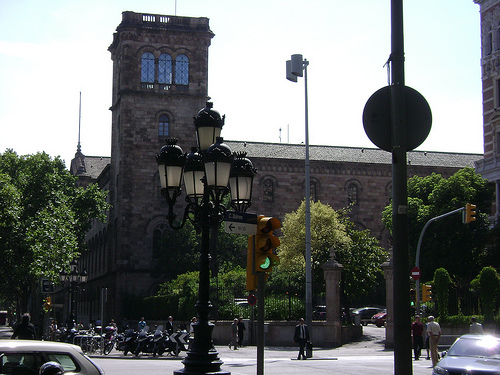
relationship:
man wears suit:
[290, 316, 312, 361] [291, 324, 311, 358]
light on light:
[257, 254, 273, 273] [252, 254, 275, 271]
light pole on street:
[285, 52, 315, 359] [41, 339, 473, 374]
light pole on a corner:
[285, 52, 315, 359] [273, 271, 391, 366]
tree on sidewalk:
[1, 148, 110, 344] [0, 321, 345, 361]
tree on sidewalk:
[0, 171, 17, 332] [0, 321, 345, 361]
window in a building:
[140, 47, 158, 87] [104, 7, 217, 340]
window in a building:
[156, 49, 173, 87] [104, 7, 217, 340]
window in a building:
[174, 51, 193, 90] [104, 7, 217, 340]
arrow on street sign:
[227, 219, 239, 232] [223, 208, 258, 239]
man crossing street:
[290, 316, 312, 361] [41, 339, 473, 374]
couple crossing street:
[227, 313, 247, 349] [41, 339, 473, 374]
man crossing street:
[425, 315, 442, 371] [41, 339, 473, 374]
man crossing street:
[410, 312, 426, 363] [41, 339, 473, 374]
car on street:
[1, 338, 104, 374] [41, 339, 473, 374]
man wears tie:
[290, 316, 312, 361] [300, 324, 306, 343]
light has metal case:
[201, 135, 233, 209] [196, 134, 236, 223]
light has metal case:
[227, 172, 253, 204] [224, 150, 255, 213]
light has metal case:
[180, 166, 206, 201] [181, 145, 205, 199]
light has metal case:
[156, 165, 185, 190] [156, 136, 187, 207]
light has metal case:
[194, 125, 223, 154] [192, 100, 227, 151]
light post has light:
[182, 213, 221, 369] [227, 172, 253, 204]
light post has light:
[182, 213, 221, 369] [180, 166, 206, 201]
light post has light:
[182, 213, 221, 369] [201, 135, 233, 209]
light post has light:
[182, 213, 221, 369] [156, 165, 185, 190]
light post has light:
[182, 213, 221, 369] [194, 125, 223, 154]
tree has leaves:
[281, 192, 352, 325] [278, 199, 352, 270]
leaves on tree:
[380, 168, 494, 271] [379, 164, 495, 315]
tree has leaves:
[1, 148, 110, 344] [18, 151, 116, 284]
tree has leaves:
[0, 171, 17, 332] [1, 170, 24, 258]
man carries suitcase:
[290, 316, 312, 361] [304, 340, 314, 362]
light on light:
[256, 234, 276, 253] [252, 254, 275, 271]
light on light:
[260, 219, 274, 236] [252, 254, 275, 271]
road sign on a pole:
[410, 266, 421, 283] [410, 202, 463, 327]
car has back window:
[1, 338, 104, 374] [47, 351, 80, 374]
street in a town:
[41, 339, 473, 374] [3, 1, 495, 372]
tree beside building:
[1, 148, 110, 344] [33, 0, 499, 344]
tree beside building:
[0, 171, 17, 332] [33, 0, 499, 344]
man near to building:
[290, 316, 312, 361] [33, 0, 499, 344]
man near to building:
[425, 315, 442, 371] [33, 0, 499, 344]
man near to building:
[410, 312, 426, 363] [33, 0, 499, 344]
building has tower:
[33, 0, 499, 344] [101, 7, 219, 327]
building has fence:
[33, 0, 499, 344] [214, 278, 324, 320]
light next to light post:
[252, 254, 275, 271] [182, 213, 221, 369]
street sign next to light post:
[223, 208, 258, 239] [182, 213, 221, 369]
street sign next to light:
[223, 208, 258, 239] [252, 254, 275, 271]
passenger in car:
[3, 354, 24, 375] [1, 338, 104, 374]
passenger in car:
[22, 354, 40, 372] [1, 338, 104, 374]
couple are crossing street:
[227, 313, 247, 349] [41, 339, 473, 374]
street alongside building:
[41, 339, 473, 374] [33, 0, 499, 344]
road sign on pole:
[410, 266, 421, 283] [410, 202, 463, 327]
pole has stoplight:
[410, 202, 463, 327] [463, 202, 477, 228]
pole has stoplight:
[410, 202, 463, 327] [419, 282, 434, 305]